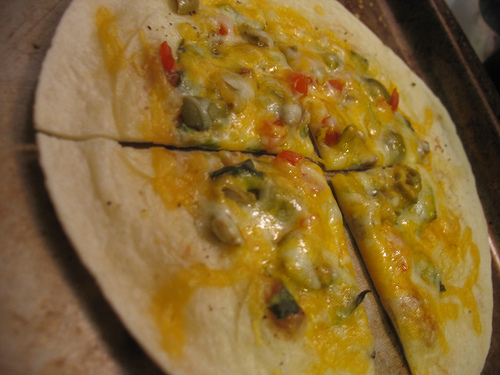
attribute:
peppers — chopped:
[184, 96, 211, 126]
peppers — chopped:
[275, 147, 300, 162]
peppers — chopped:
[217, 159, 259, 176]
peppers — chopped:
[362, 71, 392, 100]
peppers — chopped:
[388, 89, 397, 111]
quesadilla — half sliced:
[129, 57, 449, 329]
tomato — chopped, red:
[159, 37, 178, 76]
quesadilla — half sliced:
[32, 5, 499, 374]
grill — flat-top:
[3, 5, 498, 372]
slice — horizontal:
[31, 132, 378, 372]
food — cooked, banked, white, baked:
[32, 0, 491, 373]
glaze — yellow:
[93, 6, 481, 369]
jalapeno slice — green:
[391, 165, 423, 201]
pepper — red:
[159, 41, 182, 71]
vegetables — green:
[324, 45, 369, 73]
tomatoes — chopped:
[288, 71, 306, 95]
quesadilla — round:
[41, 0, 342, 192]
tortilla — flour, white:
[32, 0, 494, 374]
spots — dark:
[146, 8, 175, 38]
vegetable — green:
[181, 97, 210, 128]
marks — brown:
[5, 275, 113, 372]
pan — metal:
[2, 224, 129, 366]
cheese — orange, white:
[138, 13, 470, 350]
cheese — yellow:
[327, 171, 414, 351]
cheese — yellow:
[144, 260, 210, 353]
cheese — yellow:
[428, 215, 488, 350]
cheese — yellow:
[84, 4, 132, 77]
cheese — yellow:
[141, 144, 209, 211]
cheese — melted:
[169, 11, 451, 329]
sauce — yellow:
[92, 3, 482, 370]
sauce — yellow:
[237, 244, 271, 279]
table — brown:
[1, 5, 482, 364]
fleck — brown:
[96, 185, 126, 215]